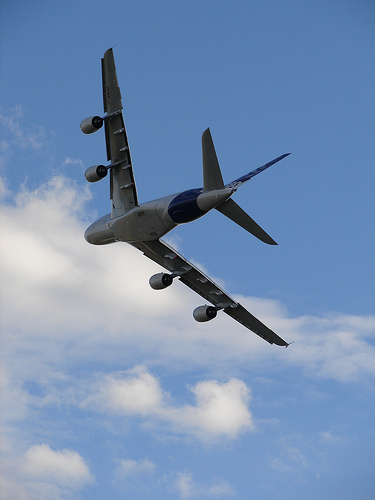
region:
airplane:
[79, 35, 301, 364]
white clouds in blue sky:
[55, 411, 92, 443]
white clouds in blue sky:
[177, 414, 204, 433]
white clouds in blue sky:
[7, 424, 55, 472]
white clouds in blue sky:
[222, 385, 264, 436]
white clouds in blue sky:
[297, 320, 333, 374]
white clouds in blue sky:
[26, 258, 61, 310]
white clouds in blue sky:
[25, 214, 57, 262]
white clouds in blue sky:
[306, 185, 354, 254]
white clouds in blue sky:
[35, 115, 64, 155]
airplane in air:
[74, 30, 295, 360]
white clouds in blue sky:
[80, 394, 130, 429]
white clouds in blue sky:
[149, 388, 214, 445]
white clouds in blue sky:
[11, 434, 59, 458]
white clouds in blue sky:
[16, 332, 79, 373]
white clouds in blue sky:
[275, 398, 314, 439]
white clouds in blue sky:
[287, 255, 332, 294]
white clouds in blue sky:
[245, 64, 306, 113]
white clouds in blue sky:
[35, 148, 75, 205]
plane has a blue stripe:
[140, 183, 218, 238]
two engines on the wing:
[136, 271, 247, 358]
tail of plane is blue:
[231, 151, 318, 218]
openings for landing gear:
[132, 201, 165, 251]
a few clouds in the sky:
[110, 361, 371, 482]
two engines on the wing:
[61, 113, 130, 219]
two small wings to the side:
[192, 130, 293, 276]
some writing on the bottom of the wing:
[101, 83, 109, 110]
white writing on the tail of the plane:
[225, 180, 249, 197]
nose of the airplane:
[80, 214, 120, 256]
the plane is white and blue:
[79, 52, 286, 320]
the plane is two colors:
[39, 107, 321, 348]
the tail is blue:
[165, 177, 207, 231]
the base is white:
[81, 201, 159, 254]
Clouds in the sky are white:
[1, 159, 283, 458]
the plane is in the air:
[13, 33, 280, 384]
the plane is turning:
[4, 51, 299, 392]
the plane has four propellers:
[77, 101, 253, 383]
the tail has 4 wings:
[162, 111, 295, 257]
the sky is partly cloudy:
[36, 70, 321, 469]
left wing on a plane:
[80, 44, 139, 218]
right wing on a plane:
[121, 240, 294, 347]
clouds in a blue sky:
[1, 101, 374, 499]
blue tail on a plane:
[223, 151, 291, 189]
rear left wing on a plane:
[201, 128, 225, 189]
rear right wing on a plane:
[210, 198, 278, 244]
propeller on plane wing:
[79, 108, 124, 133]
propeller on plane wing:
[85, 160, 108, 181]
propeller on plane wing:
[148, 271, 172, 289]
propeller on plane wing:
[191, 304, 217, 321]